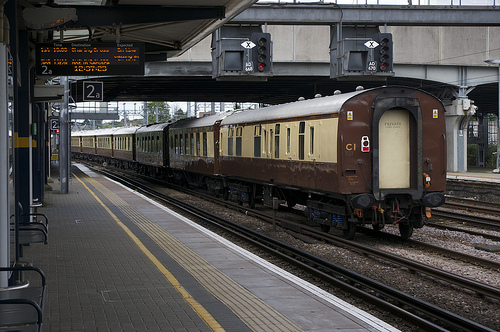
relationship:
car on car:
[219, 80, 449, 237] [74, 83, 451, 236]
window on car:
[295, 120, 306, 159] [219, 80, 449, 237]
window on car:
[273, 123, 284, 160] [219, 80, 449, 237]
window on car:
[234, 123, 245, 158] [219, 80, 449, 237]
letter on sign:
[95, 88, 101, 100] [80, 77, 107, 101]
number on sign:
[84, 84, 95, 99] [80, 77, 107, 101]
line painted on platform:
[71, 172, 224, 331] [1, 155, 366, 329]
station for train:
[1, 2, 496, 330] [74, 83, 451, 236]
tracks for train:
[368, 229, 500, 295] [74, 83, 451, 236]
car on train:
[219, 80, 449, 237] [74, 83, 451, 236]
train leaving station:
[74, 83, 451, 236] [1, 2, 496, 330]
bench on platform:
[14, 196, 50, 257] [1, 155, 366, 329]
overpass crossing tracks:
[1, 0, 500, 96] [85, 177, 499, 331]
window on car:
[253, 123, 263, 156] [219, 80, 449, 237]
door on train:
[380, 109, 412, 189] [74, 83, 451, 236]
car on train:
[166, 110, 222, 196] [74, 83, 451, 236]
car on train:
[133, 118, 167, 174] [74, 83, 451, 236]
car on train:
[113, 123, 135, 168] [74, 83, 451, 236]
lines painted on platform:
[80, 170, 299, 331] [1, 155, 366, 329]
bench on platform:
[0, 261, 48, 330] [1, 155, 366, 329]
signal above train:
[252, 31, 271, 75] [74, 83, 451, 236]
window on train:
[295, 120, 306, 159] [74, 83, 451, 236]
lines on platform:
[80, 170, 299, 331] [1, 155, 366, 329]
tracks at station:
[85, 177, 499, 331] [1, 2, 496, 330]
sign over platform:
[36, 40, 145, 78] [1, 155, 366, 329]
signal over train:
[252, 31, 271, 75] [74, 83, 451, 236]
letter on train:
[345, 140, 353, 151] [74, 83, 451, 236]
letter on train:
[351, 140, 358, 152] [74, 83, 451, 236]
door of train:
[380, 109, 412, 189] [74, 83, 451, 236]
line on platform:
[71, 172, 224, 331] [1, 155, 366, 329]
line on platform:
[103, 173, 397, 331] [1, 155, 366, 329]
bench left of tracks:
[0, 261, 48, 330] [368, 229, 500, 295]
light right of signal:
[377, 33, 394, 74] [252, 31, 271, 75]